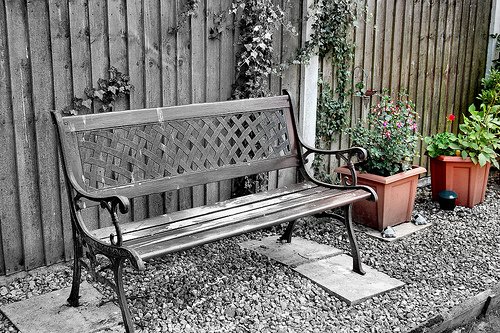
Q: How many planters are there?
A: Two.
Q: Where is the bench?
A: In front of fence.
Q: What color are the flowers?
A: Red.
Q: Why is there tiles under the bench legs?
A: Stability.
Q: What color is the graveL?
A: Gray.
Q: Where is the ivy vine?
A: On fence.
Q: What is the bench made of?
A: Cast iron and wood.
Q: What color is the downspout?
A: White.